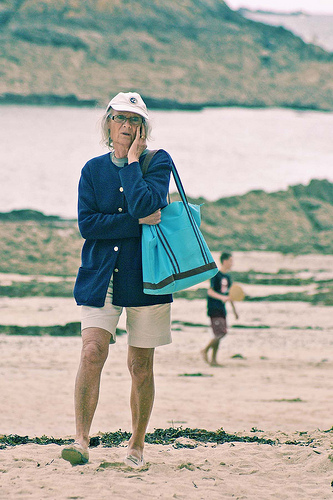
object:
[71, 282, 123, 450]
leg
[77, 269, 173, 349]
shorts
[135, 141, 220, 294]
blue tote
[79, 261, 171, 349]
short pant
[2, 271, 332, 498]
white sand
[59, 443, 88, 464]
shoe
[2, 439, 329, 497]
sand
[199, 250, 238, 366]
boy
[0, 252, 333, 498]
beach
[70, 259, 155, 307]
pockets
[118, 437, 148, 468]
left foot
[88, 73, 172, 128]
hat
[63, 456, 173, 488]
sand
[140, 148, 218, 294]
bag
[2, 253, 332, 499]
sand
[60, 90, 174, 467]
women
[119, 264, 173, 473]
left leg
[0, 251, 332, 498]
sandy area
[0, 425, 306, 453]
sea weed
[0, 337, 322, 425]
sand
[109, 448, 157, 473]
shoe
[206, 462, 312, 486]
sand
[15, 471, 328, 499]
ground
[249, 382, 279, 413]
sand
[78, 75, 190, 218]
woman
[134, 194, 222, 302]
blue bag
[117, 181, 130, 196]
button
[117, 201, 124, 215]
button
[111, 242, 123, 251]
button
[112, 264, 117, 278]
button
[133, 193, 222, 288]
lines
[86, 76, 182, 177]
head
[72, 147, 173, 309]
sweater